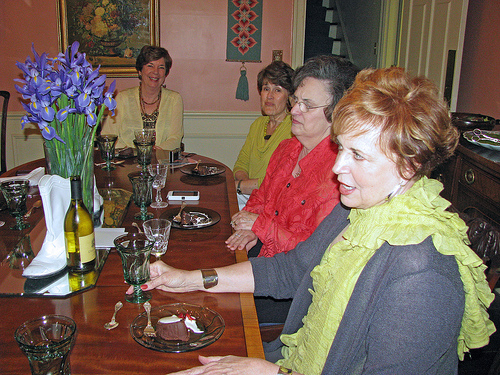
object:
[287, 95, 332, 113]
glasses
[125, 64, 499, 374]
woman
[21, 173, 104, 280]
shoe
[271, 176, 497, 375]
scarf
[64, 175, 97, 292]
bottle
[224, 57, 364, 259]
woman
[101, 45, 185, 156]
woman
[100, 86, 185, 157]
yellow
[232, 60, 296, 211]
woman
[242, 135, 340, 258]
red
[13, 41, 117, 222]
green